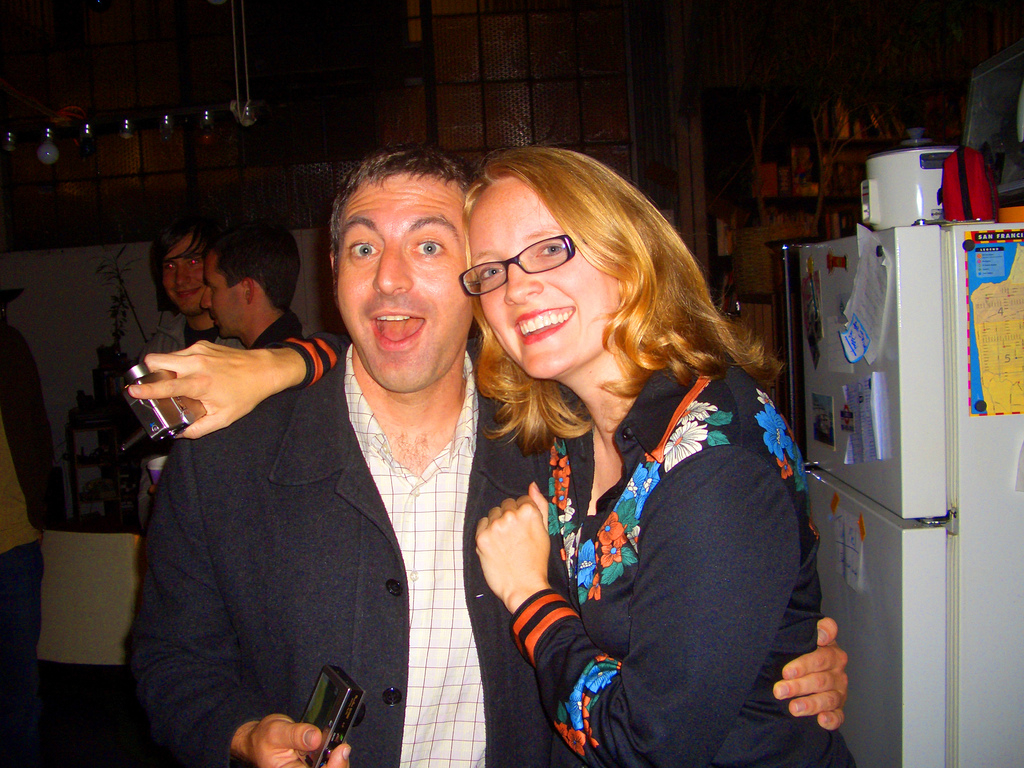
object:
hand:
[233, 714, 350, 766]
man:
[124, 145, 564, 766]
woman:
[123, 148, 863, 768]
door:
[796, 222, 946, 768]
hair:
[460, 148, 785, 458]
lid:
[901, 126, 933, 145]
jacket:
[134, 343, 586, 767]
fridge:
[797, 219, 1024, 768]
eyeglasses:
[460, 234, 577, 295]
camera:
[120, 362, 207, 453]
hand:
[129, 338, 305, 438]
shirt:
[343, 347, 490, 768]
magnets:
[811, 392, 835, 450]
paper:
[841, 370, 882, 465]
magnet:
[963, 230, 1024, 417]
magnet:
[837, 313, 870, 364]